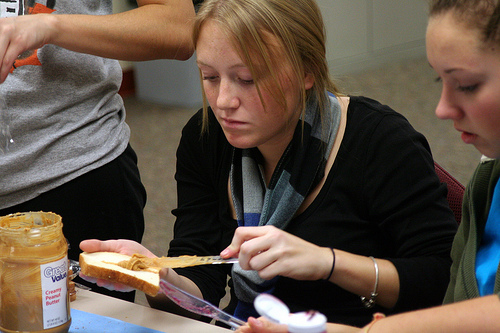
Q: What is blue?
A: Shirt.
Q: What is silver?
A: Bracelet.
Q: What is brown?
A: Peanut butter.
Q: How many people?
A: Three.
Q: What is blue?
A: Napkin.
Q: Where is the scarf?
A: Around the neck.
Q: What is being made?
A: Sandwich.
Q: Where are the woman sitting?
A: At a table.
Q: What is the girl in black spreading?
A: Peanut butter.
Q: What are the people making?
A: Sandwiches.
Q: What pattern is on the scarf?
A: Stripes.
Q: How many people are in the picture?
A: 3.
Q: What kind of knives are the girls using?
A: Plastic.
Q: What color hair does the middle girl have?
A: Blonde.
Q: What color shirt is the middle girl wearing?
A: Black.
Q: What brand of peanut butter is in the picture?
A: Great Value.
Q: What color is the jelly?
A: Grape.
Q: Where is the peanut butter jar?
A: On the table.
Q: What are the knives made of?
A: Plastic.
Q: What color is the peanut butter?
A: Brown.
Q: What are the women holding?
A: Knives.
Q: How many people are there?
A: Three.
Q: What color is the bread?
A: White and brown.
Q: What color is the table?
A: Gray.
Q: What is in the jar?
A: Peanut butter.